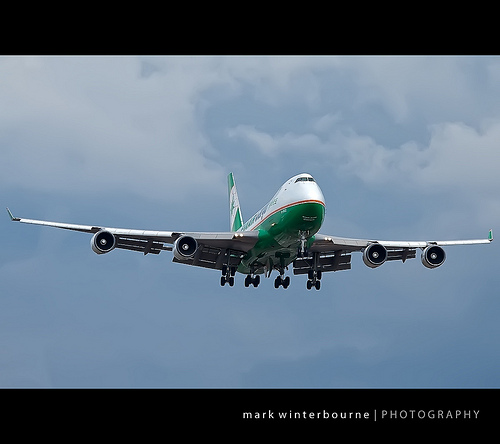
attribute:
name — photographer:
[241, 411, 372, 422]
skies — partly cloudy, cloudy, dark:
[1, 55, 499, 389]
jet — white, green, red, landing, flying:
[6, 173, 495, 289]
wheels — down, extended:
[221, 265, 322, 290]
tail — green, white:
[228, 171, 243, 234]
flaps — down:
[116, 232, 416, 274]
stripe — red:
[245, 199, 325, 230]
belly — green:
[236, 202, 325, 273]